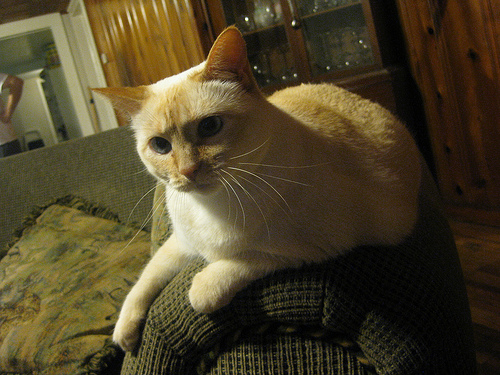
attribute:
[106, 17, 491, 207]
wall — paneled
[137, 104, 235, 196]
face — orange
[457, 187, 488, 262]
floor — is hardwood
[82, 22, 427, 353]
cat — orange, is yellow, Tan, cream-colored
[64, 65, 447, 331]
cat — cream-colored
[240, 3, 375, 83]
cups — are glass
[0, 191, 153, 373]
pillow — is tapestry, green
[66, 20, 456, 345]
cat — cream-colored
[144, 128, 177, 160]
eye — is green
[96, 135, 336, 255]
whiskers — are white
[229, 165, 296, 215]
whisker — is white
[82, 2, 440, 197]
cabinet — is wooden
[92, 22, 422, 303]
cat — cream-colored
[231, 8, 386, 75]
window — is glass